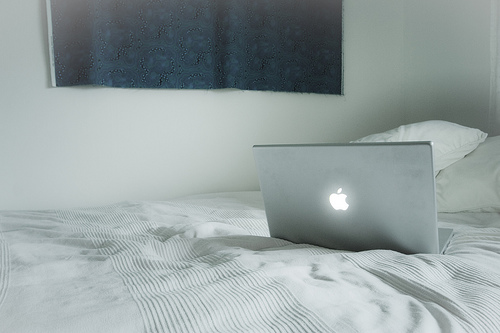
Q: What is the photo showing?
A: It is showing a bedroom.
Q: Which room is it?
A: It is a bedroom.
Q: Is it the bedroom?
A: Yes, it is the bedroom.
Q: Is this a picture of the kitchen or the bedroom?
A: It is showing the bedroom.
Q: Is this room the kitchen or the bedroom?
A: It is the bedroom.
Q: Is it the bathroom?
A: No, it is the bedroom.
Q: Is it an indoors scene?
A: Yes, it is indoors.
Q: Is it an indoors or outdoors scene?
A: It is indoors.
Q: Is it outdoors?
A: No, it is indoors.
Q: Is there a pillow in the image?
A: Yes, there is a pillow.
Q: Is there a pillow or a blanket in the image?
A: Yes, there is a pillow.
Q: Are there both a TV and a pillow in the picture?
A: No, there is a pillow but no televisions.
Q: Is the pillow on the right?
A: Yes, the pillow is on the right of the image.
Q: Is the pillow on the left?
A: No, the pillow is on the right of the image.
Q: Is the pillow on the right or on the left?
A: The pillow is on the right of the image.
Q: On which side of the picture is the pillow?
A: The pillow is on the right of the image.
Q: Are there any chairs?
A: No, there are no chairs.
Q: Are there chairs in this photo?
A: No, there are no chairs.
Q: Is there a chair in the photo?
A: No, there are no chairs.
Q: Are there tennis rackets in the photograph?
A: No, there are no tennis rackets.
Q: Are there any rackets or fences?
A: No, there are no rackets or fences.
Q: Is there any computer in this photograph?
A: Yes, there is a computer.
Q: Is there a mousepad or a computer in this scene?
A: Yes, there is a computer.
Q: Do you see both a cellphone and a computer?
A: No, there is a computer but no cell phones.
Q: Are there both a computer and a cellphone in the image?
A: No, there is a computer but no cell phones.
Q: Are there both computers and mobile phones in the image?
A: No, there is a computer but no cell phones.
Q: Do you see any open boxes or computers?
A: Yes, there is an open computer.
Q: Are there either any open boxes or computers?
A: Yes, there is an open computer.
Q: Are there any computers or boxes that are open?
A: Yes, the computer is open.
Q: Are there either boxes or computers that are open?
A: Yes, the computer is open.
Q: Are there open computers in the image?
A: Yes, there is an open computer.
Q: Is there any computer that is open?
A: Yes, there is a computer that is open.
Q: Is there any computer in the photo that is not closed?
A: Yes, there is a open computer.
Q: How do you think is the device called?
A: The device is a computer.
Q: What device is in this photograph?
A: The device is a computer.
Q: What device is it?
A: The device is a computer.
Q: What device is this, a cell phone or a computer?
A: This is a computer.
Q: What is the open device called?
A: The device is a computer.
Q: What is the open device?
A: The device is a computer.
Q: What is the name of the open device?
A: The device is a computer.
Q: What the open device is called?
A: The device is a computer.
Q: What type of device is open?
A: The device is a computer.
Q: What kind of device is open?
A: The device is a computer.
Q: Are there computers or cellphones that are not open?
A: No, there is a computer but it is open.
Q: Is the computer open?
A: Yes, the computer is open.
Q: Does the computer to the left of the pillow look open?
A: Yes, the computer is open.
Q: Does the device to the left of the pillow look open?
A: Yes, the computer is open.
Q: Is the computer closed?
A: No, the computer is open.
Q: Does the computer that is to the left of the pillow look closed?
A: No, the computer is open.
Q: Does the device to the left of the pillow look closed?
A: No, the computer is open.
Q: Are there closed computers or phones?
A: No, there is a computer but it is open.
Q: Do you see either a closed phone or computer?
A: No, there is a computer but it is open.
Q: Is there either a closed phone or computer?
A: No, there is a computer but it is open.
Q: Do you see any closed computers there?
A: No, there is a computer but it is open.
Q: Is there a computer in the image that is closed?
A: No, there is a computer but it is open.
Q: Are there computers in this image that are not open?
A: No, there is a computer but it is open.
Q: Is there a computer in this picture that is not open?
A: No, there is a computer but it is open.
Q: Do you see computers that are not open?
A: No, there is a computer but it is open.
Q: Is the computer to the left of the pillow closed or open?
A: The computer is open.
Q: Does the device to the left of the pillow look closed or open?
A: The computer is open.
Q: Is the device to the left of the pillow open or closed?
A: The computer is open.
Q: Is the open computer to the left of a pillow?
A: Yes, the computer is to the left of a pillow.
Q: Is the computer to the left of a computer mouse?
A: No, the computer is to the left of a pillow.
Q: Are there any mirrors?
A: No, there are no mirrors.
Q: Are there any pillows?
A: Yes, there is a pillow.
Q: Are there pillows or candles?
A: Yes, there is a pillow.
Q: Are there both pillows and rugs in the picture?
A: No, there is a pillow but no rugs.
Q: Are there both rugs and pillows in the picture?
A: No, there is a pillow but no rugs.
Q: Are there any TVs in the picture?
A: No, there are no tvs.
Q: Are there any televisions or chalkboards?
A: No, there are no televisions or chalkboards.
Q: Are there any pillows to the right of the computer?
A: Yes, there is a pillow to the right of the computer.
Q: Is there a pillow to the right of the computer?
A: Yes, there is a pillow to the right of the computer.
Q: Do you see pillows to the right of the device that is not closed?
A: Yes, there is a pillow to the right of the computer.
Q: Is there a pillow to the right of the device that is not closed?
A: Yes, there is a pillow to the right of the computer.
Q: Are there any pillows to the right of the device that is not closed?
A: Yes, there is a pillow to the right of the computer.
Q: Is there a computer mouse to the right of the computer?
A: No, there is a pillow to the right of the computer.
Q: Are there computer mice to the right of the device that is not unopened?
A: No, there is a pillow to the right of the computer.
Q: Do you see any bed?
A: Yes, there is a bed.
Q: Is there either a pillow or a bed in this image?
A: Yes, there is a bed.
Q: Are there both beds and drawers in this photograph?
A: No, there is a bed but no drawers.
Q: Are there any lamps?
A: No, there are no lamps.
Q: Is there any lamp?
A: No, there are no lamps.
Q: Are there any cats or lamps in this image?
A: No, there are no lamps or cats.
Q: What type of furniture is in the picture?
A: The furniture is a bed.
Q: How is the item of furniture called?
A: The piece of furniture is a bed.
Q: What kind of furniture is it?
A: The piece of furniture is a bed.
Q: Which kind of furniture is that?
A: This is a bed.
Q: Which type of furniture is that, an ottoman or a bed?
A: This is a bed.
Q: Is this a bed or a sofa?
A: This is a bed.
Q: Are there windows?
A: Yes, there is a window.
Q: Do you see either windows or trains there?
A: Yes, there is a window.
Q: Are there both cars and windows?
A: No, there is a window but no cars.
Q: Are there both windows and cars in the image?
A: No, there is a window but no cars.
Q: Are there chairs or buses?
A: No, there are no chairs or buses.